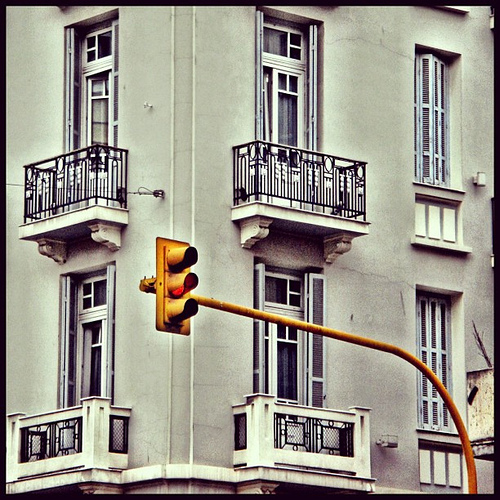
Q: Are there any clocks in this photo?
A: No, there are no clocks.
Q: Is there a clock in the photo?
A: No, there are no clocks.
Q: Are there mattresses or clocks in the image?
A: No, there are no clocks or mattresses.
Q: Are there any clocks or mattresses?
A: No, there are no clocks or mattresses.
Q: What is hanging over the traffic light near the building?
A: The wire is hanging over the traffic signal.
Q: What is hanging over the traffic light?
A: The wire is hanging over the traffic signal.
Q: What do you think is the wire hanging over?
A: The wire is hanging over the traffic signal.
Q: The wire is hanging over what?
A: The wire is hanging over the traffic signal.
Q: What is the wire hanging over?
A: The wire is hanging over the traffic signal.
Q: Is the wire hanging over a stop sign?
A: No, the wire is hanging over the signal light.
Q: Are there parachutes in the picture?
A: No, there are no parachutes.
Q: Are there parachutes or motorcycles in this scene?
A: No, there are no parachutes or motorcycles.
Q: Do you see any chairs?
A: No, there are no chairs.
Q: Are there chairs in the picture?
A: No, there are no chairs.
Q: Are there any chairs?
A: No, there are no chairs.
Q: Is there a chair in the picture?
A: No, there are no chairs.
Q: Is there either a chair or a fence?
A: No, there are no chairs or fences.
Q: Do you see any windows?
A: Yes, there is a window.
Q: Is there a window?
A: Yes, there is a window.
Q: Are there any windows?
A: Yes, there is a window.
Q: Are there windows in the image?
A: Yes, there is a window.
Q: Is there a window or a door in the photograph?
A: Yes, there is a window.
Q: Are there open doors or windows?
A: Yes, there is an open window.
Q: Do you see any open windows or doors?
A: Yes, there is an open window.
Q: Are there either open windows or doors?
A: Yes, there is an open window.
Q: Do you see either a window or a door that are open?
A: Yes, the window is open.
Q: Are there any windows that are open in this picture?
A: Yes, there is an open window.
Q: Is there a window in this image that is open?
A: Yes, there is a window that is open.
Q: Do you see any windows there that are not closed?
A: Yes, there is a open window.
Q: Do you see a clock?
A: No, there are no clocks.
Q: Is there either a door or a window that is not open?
A: No, there is a window but it is open.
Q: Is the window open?
A: Yes, the window is open.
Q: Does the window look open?
A: Yes, the window is open.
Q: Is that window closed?
A: No, the window is open.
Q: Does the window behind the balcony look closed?
A: No, the window is open.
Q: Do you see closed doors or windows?
A: No, there is a window but it is open.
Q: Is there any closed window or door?
A: No, there is a window but it is open.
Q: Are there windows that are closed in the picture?
A: No, there is a window but it is open.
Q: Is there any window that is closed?
A: No, there is a window but it is open.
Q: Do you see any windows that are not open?
A: No, there is a window but it is open.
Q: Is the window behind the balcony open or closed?
A: The window is open.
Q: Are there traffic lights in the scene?
A: Yes, there is a traffic light.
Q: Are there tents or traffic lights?
A: Yes, there is a traffic light.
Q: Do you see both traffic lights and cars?
A: No, there is a traffic light but no cars.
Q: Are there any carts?
A: No, there are no carts.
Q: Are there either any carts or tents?
A: No, there are no carts or tents.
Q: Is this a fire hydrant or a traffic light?
A: This is a traffic light.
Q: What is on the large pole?
A: The traffic light is on the pole.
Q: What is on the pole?
A: The traffic light is on the pole.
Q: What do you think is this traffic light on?
A: The traffic light is on the pole.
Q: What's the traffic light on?
A: The traffic light is on the pole.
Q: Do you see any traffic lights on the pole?
A: Yes, there is a traffic light on the pole.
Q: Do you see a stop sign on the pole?
A: No, there is a traffic light on the pole.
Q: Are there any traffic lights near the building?
A: Yes, there is a traffic light near the building.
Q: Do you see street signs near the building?
A: No, there is a traffic light near the building.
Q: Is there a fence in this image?
A: No, there are no fences.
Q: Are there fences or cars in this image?
A: No, there are no fences or cars.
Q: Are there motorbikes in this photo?
A: No, there are no motorbikes.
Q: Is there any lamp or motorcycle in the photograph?
A: No, there are no motorcycles or lamps.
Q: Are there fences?
A: No, there are no fences.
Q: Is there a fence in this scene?
A: No, there are no fences.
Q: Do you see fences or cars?
A: No, there are no fences or cars.